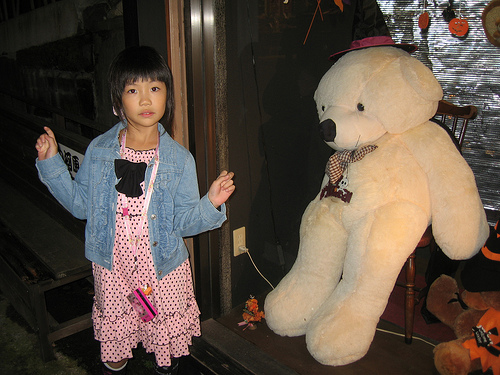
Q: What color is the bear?
A: White.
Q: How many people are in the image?
A: One.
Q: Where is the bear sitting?
A: On a chair.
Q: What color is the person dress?
A: Pink.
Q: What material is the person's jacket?
A: Denim.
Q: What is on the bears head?
A: A hat.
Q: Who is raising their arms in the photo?
A: The girl.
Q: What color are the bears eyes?
A: Black.